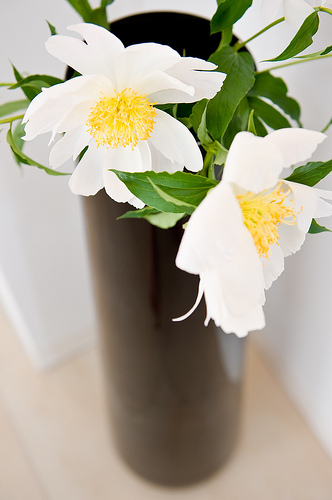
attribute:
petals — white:
[32, 20, 315, 300]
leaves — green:
[201, 18, 305, 139]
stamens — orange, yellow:
[81, 86, 166, 149]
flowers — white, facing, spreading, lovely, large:
[35, 33, 323, 343]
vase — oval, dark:
[60, 171, 247, 498]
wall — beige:
[2, 3, 325, 441]